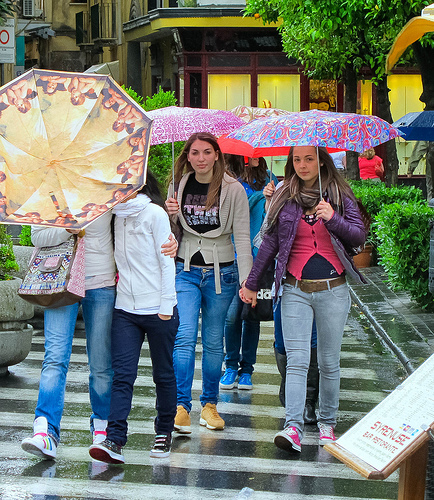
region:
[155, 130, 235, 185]
the head of a woman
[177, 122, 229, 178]
the eye of a woman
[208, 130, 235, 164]
the ear of a woman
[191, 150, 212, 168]
the nose of a woman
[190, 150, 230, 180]
the mouth of a woman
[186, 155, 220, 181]
the lips of a woman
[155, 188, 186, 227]
the hand of a woman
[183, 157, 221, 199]
the neck of a woman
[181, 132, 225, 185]
the face of a woman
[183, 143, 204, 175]
the cheek of a woman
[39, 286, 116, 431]
THESE ARE HER BLUE JEANS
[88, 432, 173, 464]
THESE ARE HER SNEAKERS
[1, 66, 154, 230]
THIS IS A UMBRELLA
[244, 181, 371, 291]
THIS IS A PURPLE JACKET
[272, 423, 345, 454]
THESE ARE PINK SHOES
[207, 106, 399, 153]
THIS IS HER UMBRELLA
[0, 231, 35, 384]
THIS IS A FLOWER POT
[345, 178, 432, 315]
THESE ARE GREEN BUSHES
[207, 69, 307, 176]
THIS IS A DOORWAY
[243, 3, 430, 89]
THIS IS A TREE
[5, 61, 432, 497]
The people are walking on the sidewalk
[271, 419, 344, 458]
The woman has on pink shoes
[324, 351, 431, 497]
The stand holding a sign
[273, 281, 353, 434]
The girl has on gray pants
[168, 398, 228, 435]
The woman has on brown shoes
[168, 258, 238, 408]
The woman has blue jeans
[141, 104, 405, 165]
The women are holding umbrella's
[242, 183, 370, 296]
The woman has on a purple jacket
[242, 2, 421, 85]
The leaves are the color green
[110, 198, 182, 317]
The person has on a white sweater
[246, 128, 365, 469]
this is a person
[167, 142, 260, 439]
this is a person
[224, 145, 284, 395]
this is a person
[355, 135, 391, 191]
this is a person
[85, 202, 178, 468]
this is a person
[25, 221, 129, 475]
this is a person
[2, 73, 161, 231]
this is an umbrella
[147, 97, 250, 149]
this is an umbrella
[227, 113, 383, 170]
this is an umbrella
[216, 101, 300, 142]
this is an umbrella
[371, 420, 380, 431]
Red letter on sign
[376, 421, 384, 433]
Red letter on sign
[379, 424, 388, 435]
Red letter on sign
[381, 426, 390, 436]
Red letter on sign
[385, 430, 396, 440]
Red letter on sign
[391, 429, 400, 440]
Red letter on sign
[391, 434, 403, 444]
Red letter on sign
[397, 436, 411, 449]
Red letter on sign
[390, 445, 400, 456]
Red letter on sign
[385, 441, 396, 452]
Red letter on sign